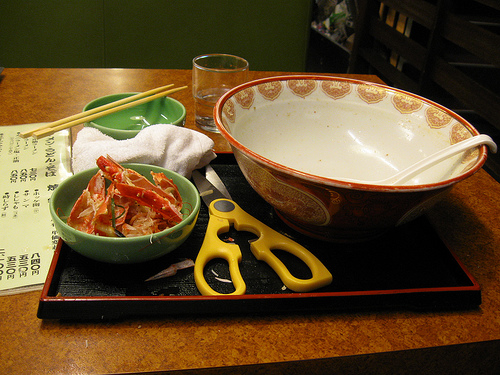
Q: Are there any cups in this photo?
A: Yes, there is a cup.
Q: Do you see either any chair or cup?
A: Yes, there is a cup.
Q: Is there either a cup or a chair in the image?
A: Yes, there is a cup.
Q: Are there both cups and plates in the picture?
A: Yes, there are both a cup and a plate.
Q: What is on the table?
A: The cup is on the table.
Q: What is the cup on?
A: The cup is on the table.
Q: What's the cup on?
A: The cup is on the table.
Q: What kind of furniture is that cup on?
A: The cup is on the table.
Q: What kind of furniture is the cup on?
A: The cup is on the table.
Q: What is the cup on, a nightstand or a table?
A: The cup is on a table.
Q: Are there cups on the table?
A: Yes, there is a cup on the table.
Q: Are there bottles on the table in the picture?
A: No, there is a cup on the table.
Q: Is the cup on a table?
A: Yes, the cup is on a table.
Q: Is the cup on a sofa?
A: No, the cup is on a table.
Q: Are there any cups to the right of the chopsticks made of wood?
A: Yes, there is a cup to the right of the chopsticks.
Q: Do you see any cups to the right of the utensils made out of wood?
A: Yes, there is a cup to the right of the chopsticks.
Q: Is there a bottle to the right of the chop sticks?
A: No, there is a cup to the right of the chop sticks.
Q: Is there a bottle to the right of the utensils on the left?
A: No, there is a cup to the right of the chop sticks.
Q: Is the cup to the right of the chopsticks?
A: Yes, the cup is to the right of the chopsticks.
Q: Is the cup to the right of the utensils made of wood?
A: Yes, the cup is to the right of the chopsticks.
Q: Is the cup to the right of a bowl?
A: Yes, the cup is to the right of a bowl.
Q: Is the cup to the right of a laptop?
A: No, the cup is to the right of a bowl.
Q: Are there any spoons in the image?
A: Yes, there is a spoon.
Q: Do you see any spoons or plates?
A: Yes, there is a spoon.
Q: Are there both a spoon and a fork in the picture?
A: No, there is a spoon but no forks.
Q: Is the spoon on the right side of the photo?
A: Yes, the spoon is on the right of the image.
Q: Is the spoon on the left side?
A: No, the spoon is on the right of the image.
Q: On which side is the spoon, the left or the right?
A: The spoon is on the right of the image.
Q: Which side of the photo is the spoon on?
A: The spoon is on the right of the image.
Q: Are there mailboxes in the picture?
A: No, there are no mailboxes.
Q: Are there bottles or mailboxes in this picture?
A: No, there are no mailboxes or bottles.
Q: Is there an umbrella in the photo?
A: No, there are no umbrellas.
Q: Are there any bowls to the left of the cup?
A: Yes, there is a bowl to the left of the cup.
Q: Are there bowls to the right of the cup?
A: No, the bowl is to the left of the cup.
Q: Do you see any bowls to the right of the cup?
A: No, the bowl is to the left of the cup.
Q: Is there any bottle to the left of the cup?
A: No, there is a bowl to the left of the cup.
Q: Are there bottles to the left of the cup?
A: No, there is a bowl to the left of the cup.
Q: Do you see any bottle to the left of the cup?
A: No, there is a bowl to the left of the cup.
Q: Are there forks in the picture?
A: No, there are no forks.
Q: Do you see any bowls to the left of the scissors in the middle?
A: Yes, there is a bowl to the left of the scissors.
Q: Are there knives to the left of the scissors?
A: No, there is a bowl to the left of the scissors.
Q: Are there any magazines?
A: No, there are no magazines.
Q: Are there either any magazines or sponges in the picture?
A: No, there are no magazines or sponges.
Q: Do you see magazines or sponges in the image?
A: No, there are no magazines or sponges.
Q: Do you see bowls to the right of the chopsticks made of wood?
A: Yes, there is a bowl to the right of the chop sticks.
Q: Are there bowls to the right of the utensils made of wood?
A: Yes, there is a bowl to the right of the chop sticks.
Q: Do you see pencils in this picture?
A: No, there are no pencils.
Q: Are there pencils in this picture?
A: No, there are no pencils.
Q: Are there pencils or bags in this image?
A: No, there are no pencils or bags.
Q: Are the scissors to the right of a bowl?
A: Yes, the scissors are to the right of a bowl.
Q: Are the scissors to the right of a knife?
A: No, the scissors are to the right of a bowl.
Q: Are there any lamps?
A: No, there are no lamps.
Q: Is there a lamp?
A: No, there are no lamps.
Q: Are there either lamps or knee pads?
A: No, there are no lamps or knee pads.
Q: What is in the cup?
A: The water is in the cup.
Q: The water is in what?
A: The water is in the cup.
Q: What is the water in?
A: The water is in the cup.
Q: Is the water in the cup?
A: Yes, the water is in the cup.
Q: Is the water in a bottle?
A: No, the water is in the cup.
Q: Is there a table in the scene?
A: Yes, there is a table.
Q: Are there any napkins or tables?
A: Yes, there is a table.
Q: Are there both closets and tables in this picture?
A: No, there is a table but no closets.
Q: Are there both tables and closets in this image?
A: No, there is a table but no closets.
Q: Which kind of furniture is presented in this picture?
A: The furniture is a table.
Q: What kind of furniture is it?
A: The piece of furniture is a table.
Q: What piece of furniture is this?
A: This is a table.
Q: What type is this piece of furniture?
A: This is a table.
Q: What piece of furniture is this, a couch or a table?
A: This is a table.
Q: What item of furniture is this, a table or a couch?
A: This is a table.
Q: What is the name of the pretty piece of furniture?
A: The piece of furniture is a table.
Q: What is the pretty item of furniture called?
A: The piece of furniture is a table.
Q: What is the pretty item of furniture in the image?
A: The piece of furniture is a table.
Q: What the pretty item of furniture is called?
A: The piece of furniture is a table.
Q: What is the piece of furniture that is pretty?
A: The piece of furniture is a table.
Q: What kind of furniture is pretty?
A: The furniture is a table.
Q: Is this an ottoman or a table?
A: This is a table.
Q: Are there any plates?
A: Yes, there is a plate.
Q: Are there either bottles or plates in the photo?
A: Yes, there is a plate.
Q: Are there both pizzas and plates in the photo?
A: No, there is a plate but no pizzas.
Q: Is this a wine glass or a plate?
A: This is a plate.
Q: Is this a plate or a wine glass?
A: This is a plate.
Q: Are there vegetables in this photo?
A: No, there are no vegetables.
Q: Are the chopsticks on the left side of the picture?
A: Yes, the chopsticks are on the left of the image.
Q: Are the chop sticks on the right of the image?
A: No, the chop sticks are on the left of the image.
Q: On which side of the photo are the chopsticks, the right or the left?
A: The chopsticks are on the left of the image.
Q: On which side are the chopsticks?
A: The chopsticks are on the left of the image.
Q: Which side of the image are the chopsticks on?
A: The chopsticks are on the left of the image.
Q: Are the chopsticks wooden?
A: Yes, the chopsticks are wooden.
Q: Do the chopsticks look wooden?
A: Yes, the chopsticks are wooden.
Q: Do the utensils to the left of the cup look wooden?
A: Yes, the chopsticks are wooden.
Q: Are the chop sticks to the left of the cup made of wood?
A: Yes, the chopsticks are made of wood.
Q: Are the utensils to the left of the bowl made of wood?
A: Yes, the chopsticks are made of wood.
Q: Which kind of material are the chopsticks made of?
A: The chopsticks are made of wood.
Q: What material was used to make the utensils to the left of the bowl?
A: The chopsticks are made of wood.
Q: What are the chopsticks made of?
A: The chopsticks are made of wood.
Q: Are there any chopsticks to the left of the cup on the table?
A: Yes, there are chopsticks to the left of the cup.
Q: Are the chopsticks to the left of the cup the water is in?
A: Yes, the chopsticks are to the left of the cup.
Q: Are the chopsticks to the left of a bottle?
A: No, the chopsticks are to the left of the cup.